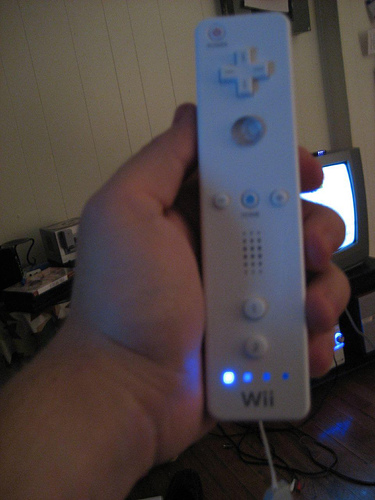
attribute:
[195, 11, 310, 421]
remote — white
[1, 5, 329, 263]
wall — white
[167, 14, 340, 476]
controller — on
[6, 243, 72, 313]
table — cluttered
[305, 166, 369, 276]
tv — small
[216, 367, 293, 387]
lights — blue 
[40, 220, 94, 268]
box — cardboard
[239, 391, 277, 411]
graphic — part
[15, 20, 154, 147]
wall — tan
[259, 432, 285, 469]
wire — part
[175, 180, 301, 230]
buttons — white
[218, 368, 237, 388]
light — blue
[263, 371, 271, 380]
light — blue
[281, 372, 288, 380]
light — blue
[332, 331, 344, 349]
light — blue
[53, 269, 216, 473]
wrist — part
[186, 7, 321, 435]
controller — white